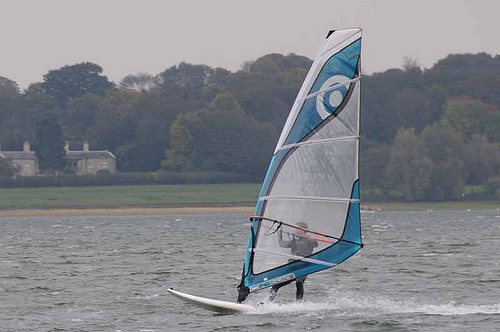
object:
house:
[0, 140, 119, 186]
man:
[277, 222, 326, 303]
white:
[244, 304, 320, 311]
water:
[2, 214, 162, 332]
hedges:
[0, 174, 16, 182]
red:
[451, 94, 465, 100]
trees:
[161, 108, 196, 180]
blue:
[344, 55, 351, 76]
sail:
[245, 28, 365, 290]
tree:
[116, 75, 162, 95]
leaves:
[121, 76, 122, 81]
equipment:
[166, 27, 365, 310]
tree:
[33, 107, 70, 179]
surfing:
[162, 221, 465, 316]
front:
[164, 280, 252, 314]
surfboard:
[163, 284, 385, 319]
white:
[318, 108, 324, 113]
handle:
[248, 212, 365, 245]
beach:
[0, 203, 269, 218]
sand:
[247, 206, 255, 214]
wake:
[423, 299, 441, 314]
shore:
[365, 178, 499, 212]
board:
[167, 276, 312, 321]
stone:
[98, 160, 107, 166]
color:
[92, 81, 98, 88]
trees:
[389, 105, 431, 202]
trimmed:
[3, 184, 92, 203]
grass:
[3, 183, 101, 202]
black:
[287, 238, 314, 256]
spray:
[258, 285, 276, 306]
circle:
[313, 73, 358, 119]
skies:
[2, 2, 136, 54]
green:
[0, 186, 12, 193]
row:
[0, 172, 264, 189]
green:
[71, 178, 86, 184]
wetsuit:
[273, 229, 317, 291]